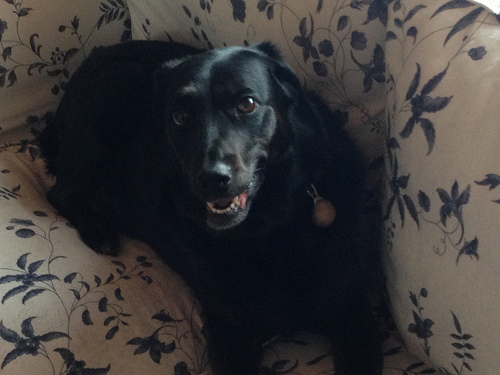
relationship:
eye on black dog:
[163, 104, 195, 132] [44, 38, 384, 373]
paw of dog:
[58, 186, 128, 266] [44, 16, 439, 372]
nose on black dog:
[196, 158, 235, 194] [44, 38, 384, 373]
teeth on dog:
[202, 187, 249, 212] [33, 38, 383, 373]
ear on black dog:
[266, 54, 338, 156] [44, 38, 384, 373]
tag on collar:
[296, 180, 336, 226] [152, 66, 346, 229]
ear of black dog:
[266, 54, 317, 159] [44, 38, 384, 373]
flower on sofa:
[291, 15, 325, 62] [3, 4, 498, 354]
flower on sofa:
[4, 312, 73, 374] [3, 4, 498, 354]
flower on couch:
[392, 64, 456, 153] [8, 0, 495, 374]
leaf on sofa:
[443, 307, 465, 335] [3, 4, 498, 354]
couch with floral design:
[8, 0, 495, 374] [438, 176, 467, 236]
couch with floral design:
[8, 0, 495, 374] [357, 52, 388, 89]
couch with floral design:
[8, 0, 495, 374] [403, 306, 435, 352]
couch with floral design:
[8, 0, 495, 374] [131, 318, 170, 362]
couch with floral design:
[8, 0, 495, 374] [2, 250, 52, 310]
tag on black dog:
[303, 183, 336, 226] [44, 38, 384, 373]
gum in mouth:
[239, 192, 249, 209] [203, 185, 258, 226]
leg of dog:
[40, 156, 140, 262] [144, 50, 389, 230]